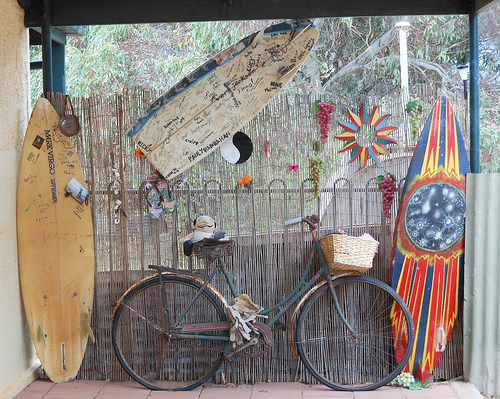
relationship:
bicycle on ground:
[110, 214, 415, 391] [15, 365, 483, 395]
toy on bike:
[179, 211, 231, 250] [107, 207, 419, 394]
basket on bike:
[319, 230, 379, 272] [107, 207, 419, 394]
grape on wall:
[310, 100, 343, 142] [38, 87, 468, 384]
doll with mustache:
[174, 214, 230, 259] [194, 221, 215, 231]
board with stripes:
[393, 99, 465, 384] [394, 101, 462, 383]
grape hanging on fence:
[316, 99, 334, 143] [33, 89, 417, 382]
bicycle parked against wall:
[107, 215, 417, 397] [37, 8, 469, 371]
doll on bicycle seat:
[180, 214, 227, 256] [192, 235, 231, 265]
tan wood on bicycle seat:
[17, 98, 97, 387] [189, 236, 241, 256]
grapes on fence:
[375, 173, 395, 220] [37, 91, 464, 383]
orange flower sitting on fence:
[234, 172, 254, 189] [81, 178, 469, 387]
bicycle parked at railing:
[107, 215, 417, 397] [37, 175, 405, 393]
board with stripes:
[388, 92, 471, 384] [392, 252, 460, 377]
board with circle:
[388, 92, 471, 384] [403, 182, 466, 250]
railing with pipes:
[95, 188, 408, 394] [112, 178, 387, 382]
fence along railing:
[136, 99, 477, 387] [95, 188, 408, 394]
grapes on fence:
[380, 177, 398, 218] [81, 178, 469, 387]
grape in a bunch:
[316, 99, 334, 143] [303, 149, 327, 200]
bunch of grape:
[303, 149, 327, 200] [316, 99, 334, 143]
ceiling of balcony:
[23, 2, 473, 23] [4, 7, 484, 384]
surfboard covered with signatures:
[128, 16, 318, 181] [161, 32, 304, 115]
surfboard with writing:
[128, 16, 318, 181] [127, 28, 319, 159]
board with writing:
[16, 97, 96, 384] [25, 120, 96, 238]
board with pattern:
[388, 92, 471, 384] [402, 168, 466, 258]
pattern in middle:
[402, 168, 466, 258] [392, 157, 472, 272]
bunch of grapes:
[309, 92, 339, 143] [309, 93, 345, 143]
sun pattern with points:
[334, 103, 398, 169] [335, 105, 397, 165]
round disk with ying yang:
[218, 128, 255, 165] [219, 130, 257, 163]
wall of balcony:
[7, 17, 27, 397] [4, 7, 484, 384]